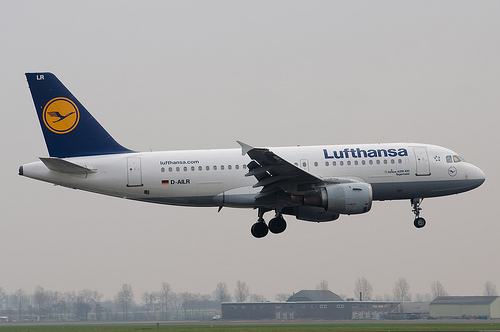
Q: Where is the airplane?
A: In the sky.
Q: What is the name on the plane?
A: Lufthansa.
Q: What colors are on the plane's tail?
A: Yellow and blue.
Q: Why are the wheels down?
A: The plane is taking off or landing.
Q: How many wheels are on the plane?
A: Three.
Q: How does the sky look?
A: Hazy.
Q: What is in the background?
A: Buildings.